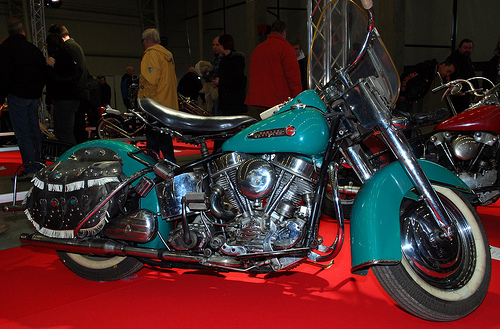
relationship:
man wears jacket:
[241, 13, 310, 123] [242, 31, 305, 111]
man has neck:
[211, 33, 248, 152] [222, 51, 237, 60]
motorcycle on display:
[7, 1, 484, 324] [3, 61, 496, 321]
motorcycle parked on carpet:
[7, 1, 484, 324] [3, 138, 498, 328]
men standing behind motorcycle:
[3, 16, 86, 183] [7, 1, 484, 324]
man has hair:
[136, 28, 180, 166] [142, 26, 161, 51]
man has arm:
[130, 17, 180, 145] [139, 44, 160, 92]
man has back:
[136, 28, 180, 166] [153, 47, 177, 99]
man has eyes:
[211, 33, 248, 152] [209, 40, 222, 48]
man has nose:
[208, 22, 248, 105] [214, 41, 226, 57]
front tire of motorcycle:
[364, 174, 494, 324] [7, 1, 484, 324]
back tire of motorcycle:
[46, 146, 148, 281] [7, 1, 484, 324]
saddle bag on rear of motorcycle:
[22, 157, 129, 245] [2, 1, 493, 322]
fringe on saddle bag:
[27, 174, 122, 192] [11, 157, 126, 241]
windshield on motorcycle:
[317, 1, 411, 132] [23, 60, 497, 327]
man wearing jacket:
[136, 28, 180, 166] [137, 45, 179, 115]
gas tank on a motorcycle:
[223, 103, 328, 155] [7, 1, 484, 324]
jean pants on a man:
[5, 92, 44, 167] [0, 19, 50, 179]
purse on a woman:
[51, 50, 78, 88] [42, 30, 89, 154]